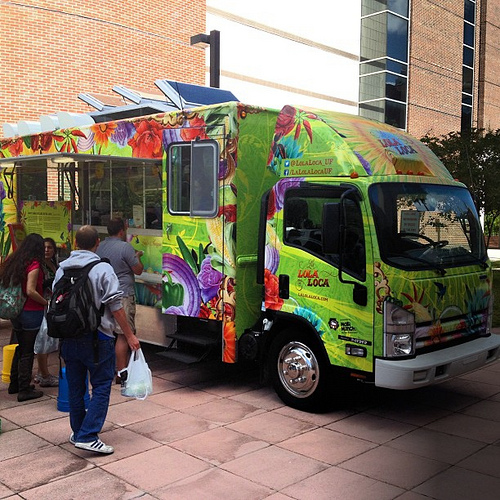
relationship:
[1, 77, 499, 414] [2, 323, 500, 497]
food truck on road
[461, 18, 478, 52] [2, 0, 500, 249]
window on building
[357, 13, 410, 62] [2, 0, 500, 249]
window on building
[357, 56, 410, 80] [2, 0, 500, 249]
window on building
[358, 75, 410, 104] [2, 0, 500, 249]
window on building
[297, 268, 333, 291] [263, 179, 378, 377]
logo on door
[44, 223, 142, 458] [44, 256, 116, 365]
man has a backpack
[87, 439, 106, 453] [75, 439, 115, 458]
stripes are on sneaker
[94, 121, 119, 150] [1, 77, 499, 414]
design on food truck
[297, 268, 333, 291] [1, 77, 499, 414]
lola loca on food truck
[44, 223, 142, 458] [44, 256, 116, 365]
man wearing a backpack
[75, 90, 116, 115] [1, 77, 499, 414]
vent on top of food truck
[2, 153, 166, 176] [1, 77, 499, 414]
awning on top of food truck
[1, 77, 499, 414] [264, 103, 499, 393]
food truck has a cab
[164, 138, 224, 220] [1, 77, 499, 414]
window on food truck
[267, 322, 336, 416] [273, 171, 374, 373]
wheel on passenger side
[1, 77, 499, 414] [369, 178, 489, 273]
food truck has a windshield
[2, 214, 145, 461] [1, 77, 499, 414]
people are in line at food truck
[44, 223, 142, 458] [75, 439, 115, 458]
man has a shoe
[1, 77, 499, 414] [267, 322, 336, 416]
food truck has a wheel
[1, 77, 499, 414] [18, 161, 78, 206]
food truck has a back window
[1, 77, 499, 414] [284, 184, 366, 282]
food truck has a window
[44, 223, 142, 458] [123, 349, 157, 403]
man has a bag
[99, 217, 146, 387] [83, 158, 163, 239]
man at window